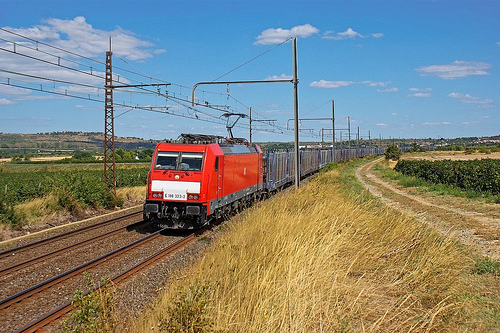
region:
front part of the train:
[136, 131, 228, 234]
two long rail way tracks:
[39, 202, 151, 304]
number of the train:
[146, 177, 188, 202]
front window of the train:
[148, 148, 223, 173]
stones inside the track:
[63, 277, 100, 294]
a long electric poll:
[282, 18, 317, 186]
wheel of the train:
[186, 213, 220, 238]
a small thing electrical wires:
[21, 51, 261, 126]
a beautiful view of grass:
[278, 188, 370, 331]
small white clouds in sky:
[238, 20, 488, 118]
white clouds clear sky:
[48, 13, 147, 73]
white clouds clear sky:
[21, 14, 233, 90]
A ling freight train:
[137, 141, 440, 248]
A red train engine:
[140, 137, 260, 230]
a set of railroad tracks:
[3, 201, 195, 331]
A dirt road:
[351, 154, 497, 266]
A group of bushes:
[392, 149, 499, 206]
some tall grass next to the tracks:
[196, 156, 360, 331]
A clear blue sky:
[6, 0, 498, 133]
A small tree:
[379, 145, 404, 160]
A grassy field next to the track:
[3, 162, 177, 232]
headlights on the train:
[148, 184, 200, 202]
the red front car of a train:
[150, 133, 265, 226]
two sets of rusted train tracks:
[21, 237, 113, 304]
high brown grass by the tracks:
[232, 194, 401, 330]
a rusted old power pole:
[32, 27, 141, 177]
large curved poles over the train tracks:
[177, 44, 355, 186]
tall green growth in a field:
[386, 145, 497, 191]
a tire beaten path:
[365, 161, 409, 225]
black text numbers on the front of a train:
[159, 187, 190, 200]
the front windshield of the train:
[157, 148, 202, 170]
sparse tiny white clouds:
[316, 42, 464, 128]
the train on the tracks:
[140, 125, 277, 242]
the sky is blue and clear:
[400, 17, 460, 49]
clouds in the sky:
[5, 10, 155, 52]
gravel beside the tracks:
[155, 240, 205, 260]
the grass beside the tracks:
[230, 210, 405, 320]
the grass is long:
[211, 214, 361, 315]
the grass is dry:
[223, 220, 364, 332]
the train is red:
[138, 135, 273, 215]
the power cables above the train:
[97, 72, 258, 137]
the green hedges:
[396, 152, 498, 189]